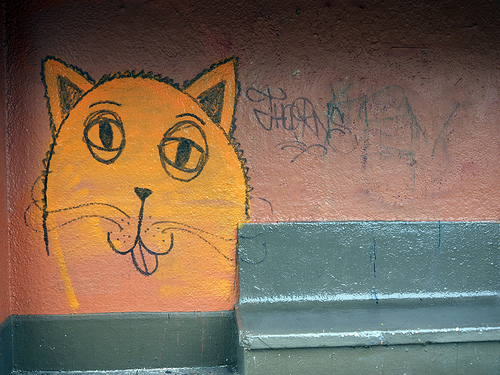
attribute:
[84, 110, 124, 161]
eye — Black 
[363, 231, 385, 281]
streak — blue, paint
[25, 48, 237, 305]
cat — yellow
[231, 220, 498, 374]
bench — green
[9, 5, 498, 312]
wall — brown